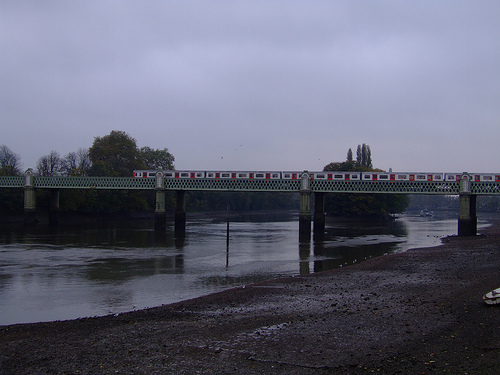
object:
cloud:
[0, 0, 500, 173]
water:
[0, 0, 484, 130]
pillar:
[299, 191, 311, 244]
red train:
[132, 170, 499, 182]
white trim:
[195, 172, 205, 179]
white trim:
[236, 172, 249, 178]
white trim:
[314, 173, 328, 180]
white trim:
[377, 174, 390, 181]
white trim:
[414, 174, 426, 181]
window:
[181, 173, 189, 178]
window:
[197, 173, 202, 177]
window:
[222, 173, 230, 177]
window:
[250, 174, 264, 178]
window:
[334, 175, 343, 179]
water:
[0, 210, 491, 329]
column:
[299, 192, 325, 243]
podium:
[91, 246, 195, 300]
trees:
[0, 130, 175, 214]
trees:
[321, 143, 412, 217]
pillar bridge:
[154, 191, 166, 233]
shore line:
[0, 211, 483, 232]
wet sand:
[3, 225, 497, 367]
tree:
[86, 129, 175, 177]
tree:
[38, 148, 93, 177]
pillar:
[458, 194, 477, 237]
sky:
[0, 1, 498, 174]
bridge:
[0, 176, 500, 243]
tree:
[322, 162, 412, 217]